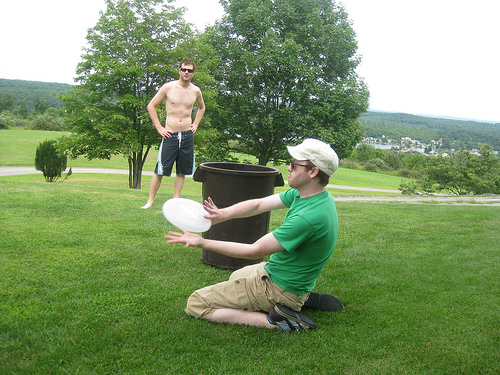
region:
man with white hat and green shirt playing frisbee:
[240, 120, 377, 303]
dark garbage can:
[177, 135, 303, 285]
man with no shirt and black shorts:
[138, 37, 228, 188]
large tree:
[206, 11, 407, 143]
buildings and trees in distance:
[355, 115, 475, 192]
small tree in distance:
[23, 123, 83, 196]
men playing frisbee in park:
[112, 21, 377, 351]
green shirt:
[265, 196, 351, 304]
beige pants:
[185, 245, 320, 351]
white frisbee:
[157, 187, 238, 249]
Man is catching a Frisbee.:
[156, 188, 219, 234]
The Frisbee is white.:
[163, 198, 223, 237]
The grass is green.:
[45, 270, 130, 345]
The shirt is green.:
[283, 215, 319, 289]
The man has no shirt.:
[151, 77, 206, 127]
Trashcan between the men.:
[193, 160, 275, 259]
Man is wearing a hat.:
[282, 138, 334, 176]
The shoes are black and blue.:
[256, 285, 345, 338]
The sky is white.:
[386, 30, 453, 100]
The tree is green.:
[232, 27, 324, 124]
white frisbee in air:
[163, 193, 214, 238]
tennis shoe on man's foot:
[265, 303, 325, 336]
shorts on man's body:
[155, 127, 199, 178]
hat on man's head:
[287, 137, 340, 177]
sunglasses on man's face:
[178, 66, 194, 75]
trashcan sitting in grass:
[191, 157, 283, 275]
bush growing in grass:
[33, 136, 73, 184]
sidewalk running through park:
[1, 161, 208, 182]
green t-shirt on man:
[263, 182, 339, 300]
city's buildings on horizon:
[368, 130, 450, 147]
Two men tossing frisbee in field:
[142, 67, 323, 262]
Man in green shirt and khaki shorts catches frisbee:
[165, 170, 340, 312]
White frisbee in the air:
[141, 191, 217, 236]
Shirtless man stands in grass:
[150, 56, 202, 181]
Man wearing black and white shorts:
[145, 115, 200, 175]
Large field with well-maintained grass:
[30, 50, 420, 325]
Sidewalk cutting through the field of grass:
[0, 120, 225, 175]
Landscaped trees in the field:
[0, 65, 350, 175]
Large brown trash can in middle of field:
[182, 136, 269, 281]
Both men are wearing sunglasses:
[180, 60, 331, 180]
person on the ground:
[168, 122, 369, 323]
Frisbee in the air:
[162, 188, 222, 249]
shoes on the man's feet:
[272, 303, 314, 340]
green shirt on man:
[258, 201, 352, 276]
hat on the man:
[281, 118, 364, 172]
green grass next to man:
[58, 228, 144, 288]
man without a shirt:
[148, 48, 228, 133]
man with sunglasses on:
[176, 56, 208, 85]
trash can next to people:
[196, 124, 294, 192]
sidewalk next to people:
[80, 158, 111, 190]